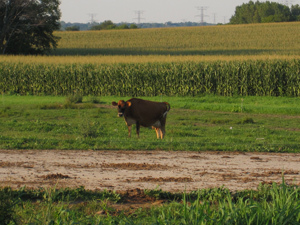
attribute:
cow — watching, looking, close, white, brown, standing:
[110, 92, 181, 140]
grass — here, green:
[26, 95, 93, 142]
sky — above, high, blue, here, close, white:
[110, 4, 137, 17]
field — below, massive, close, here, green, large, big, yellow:
[104, 29, 213, 77]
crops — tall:
[4, 22, 299, 94]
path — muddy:
[1, 146, 298, 191]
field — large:
[2, 22, 299, 94]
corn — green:
[3, 20, 299, 93]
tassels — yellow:
[0, 21, 299, 73]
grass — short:
[4, 94, 299, 151]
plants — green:
[1, 19, 299, 93]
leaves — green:
[0, 0, 61, 51]